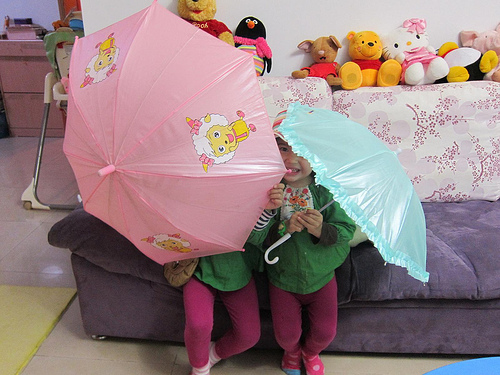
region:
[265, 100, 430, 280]
An umbrella with a blue top and white handle.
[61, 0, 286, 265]
Pink umbrella that is large.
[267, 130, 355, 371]
A little girl under a blue umbrella with a green jacket on.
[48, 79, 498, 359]
A long purple couch.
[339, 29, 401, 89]
A short haired Winnie the Pooh you can see all of.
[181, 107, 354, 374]
Two girls in green and purple under umbrellas.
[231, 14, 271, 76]
A black penguin with orange beak and pink scarf.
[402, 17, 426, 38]
A pink bow on Hello Kitty.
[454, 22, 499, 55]
The head of a pink pig.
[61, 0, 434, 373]
Two kids are holding umbrellas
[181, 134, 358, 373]
Two kids are wearing matching outfits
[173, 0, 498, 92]
Many stuffed animals against the wall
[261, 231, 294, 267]
White handle of an umbrella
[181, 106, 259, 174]
Sheep picture on an umbrella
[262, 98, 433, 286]
An umbrella is blue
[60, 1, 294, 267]
A pink colored umbrella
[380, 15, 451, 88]
Hello Kitty doll wearing a pink outfit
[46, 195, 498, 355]
A purple colored couch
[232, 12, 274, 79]
Black penguin wearing a pink scarf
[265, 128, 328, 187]
head of a person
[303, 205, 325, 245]
hand of a person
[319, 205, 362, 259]
arm of a person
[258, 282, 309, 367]
leg of a person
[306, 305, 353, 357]
leg of a person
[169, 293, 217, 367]
leg of a person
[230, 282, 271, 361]
leg of a person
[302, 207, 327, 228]
finger of a person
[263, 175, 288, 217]
finger of a person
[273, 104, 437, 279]
light blue umbrella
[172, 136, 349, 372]
girls wearing matching outfits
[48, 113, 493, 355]
purple couch children are standing in front of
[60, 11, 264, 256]
pink umbrella with characters on it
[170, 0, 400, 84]
winnie the pooh toys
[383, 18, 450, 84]
hello kitty stuffed toy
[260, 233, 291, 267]
white handle of the blue umbrella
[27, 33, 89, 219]
highchair in the kitchen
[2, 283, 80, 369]
yellow rug on the floor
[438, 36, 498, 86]
stuffed penguin toy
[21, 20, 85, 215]
part of a baby chair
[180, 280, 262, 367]
a girl's pink leggings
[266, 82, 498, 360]
part of a purple and white couch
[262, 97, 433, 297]
a blue umbrella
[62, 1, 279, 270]
a pink umbrella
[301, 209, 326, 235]
the hand of a girl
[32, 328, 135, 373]
part of a white tile floor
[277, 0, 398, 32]
part of a painted white wall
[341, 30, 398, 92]
a small pooh bear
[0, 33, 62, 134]
a small brown drawer cabinet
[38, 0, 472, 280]
a pair of umbrellas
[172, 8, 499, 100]
a group of stuffed animals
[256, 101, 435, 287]
a large open umbrella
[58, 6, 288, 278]
a large open umbrella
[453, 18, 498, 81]
a toy stuffed animal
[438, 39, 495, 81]
a toy stuffed animal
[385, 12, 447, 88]
a toy stuffed animal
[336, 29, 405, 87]
a toy stuffed animal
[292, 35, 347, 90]
a toy stuffed animal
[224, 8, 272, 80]
a toy stuffed animal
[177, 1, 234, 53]
a toy stuffed animal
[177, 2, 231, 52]
A toy stuffed animal.